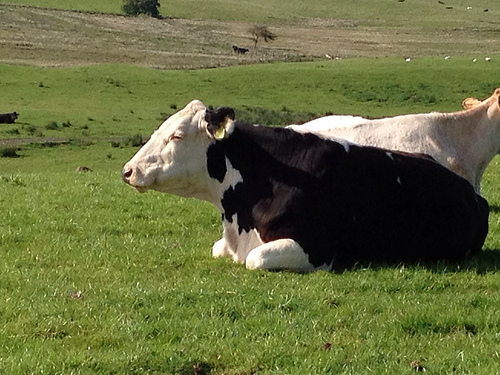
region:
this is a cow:
[109, 84, 489, 314]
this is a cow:
[297, 90, 499, 216]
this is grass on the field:
[174, 271, 269, 344]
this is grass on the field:
[286, 295, 373, 354]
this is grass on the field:
[68, 232, 170, 334]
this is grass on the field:
[46, 139, 121, 229]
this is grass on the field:
[119, 289, 186, 331]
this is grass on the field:
[361, 285, 464, 348]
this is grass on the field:
[106, 267, 230, 352]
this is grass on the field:
[246, 303, 318, 358]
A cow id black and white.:
[120, 100, 492, 270]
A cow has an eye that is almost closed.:
[119, 97, 491, 268]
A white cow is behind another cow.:
[279, 91, 499, 201]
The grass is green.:
[0, 57, 499, 369]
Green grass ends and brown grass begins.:
[0, 5, 499, 70]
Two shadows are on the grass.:
[435, 202, 497, 267]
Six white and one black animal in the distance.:
[230, 40, 490, 60]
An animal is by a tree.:
[230, 24, 281, 56]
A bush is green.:
[114, 1, 169, 16]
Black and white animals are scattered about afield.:
[232, 2, 497, 73]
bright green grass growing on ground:
[33, 192, 163, 284]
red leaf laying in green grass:
[59, 276, 98, 313]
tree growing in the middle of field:
[240, 18, 284, 47]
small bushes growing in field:
[43, 111, 75, 132]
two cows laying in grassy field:
[101, 85, 498, 301]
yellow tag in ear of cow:
[210, 122, 227, 142]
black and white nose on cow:
[112, 162, 150, 202]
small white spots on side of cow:
[373, 148, 403, 193]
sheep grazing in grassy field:
[373, 38, 497, 75]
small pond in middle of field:
[3, 128, 81, 160]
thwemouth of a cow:
[101, 137, 162, 191]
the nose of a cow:
[117, 153, 151, 200]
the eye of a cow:
[162, 114, 199, 154]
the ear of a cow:
[178, 57, 250, 159]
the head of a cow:
[118, 89, 232, 205]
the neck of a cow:
[171, 117, 301, 244]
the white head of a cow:
[122, 97, 256, 209]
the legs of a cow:
[232, 218, 329, 288]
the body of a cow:
[185, 147, 420, 312]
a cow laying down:
[107, 57, 435, 312]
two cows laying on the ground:
[100, 88, 497, 300]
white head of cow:
[124, 93, 244, 201]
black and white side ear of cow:
[209, 99, 245, 137]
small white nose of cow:
[117, 165, 154, 188]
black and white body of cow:
[216, 112, 488, 279]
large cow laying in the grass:
[88, 118, 494, 281]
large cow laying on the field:
[107, 96, 497, 296]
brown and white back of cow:
[339, 88, 489, 159]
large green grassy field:
[0, 70, 111, 352]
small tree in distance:
[209, 15, 308, 58]